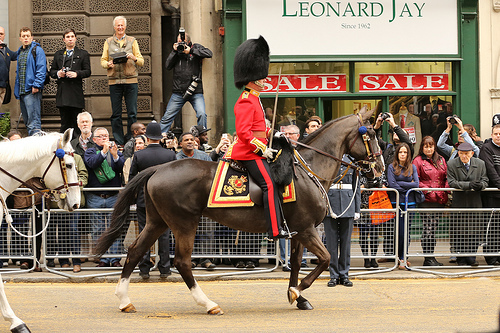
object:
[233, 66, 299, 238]
man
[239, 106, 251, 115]
red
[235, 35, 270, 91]
helmet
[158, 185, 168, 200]
brown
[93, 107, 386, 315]
horse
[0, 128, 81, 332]
horse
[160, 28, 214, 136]
person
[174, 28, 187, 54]
camera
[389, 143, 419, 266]
person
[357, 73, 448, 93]
sign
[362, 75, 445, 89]
sale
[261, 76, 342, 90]
text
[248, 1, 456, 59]
sign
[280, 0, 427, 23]
text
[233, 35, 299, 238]
guard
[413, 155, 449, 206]
coat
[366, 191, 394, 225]
bag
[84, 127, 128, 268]
man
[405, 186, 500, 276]
barrier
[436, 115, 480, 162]
person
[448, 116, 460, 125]
camera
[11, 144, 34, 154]
white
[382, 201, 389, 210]
orange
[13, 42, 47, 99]
jacket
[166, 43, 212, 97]
jacket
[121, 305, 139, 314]
hooves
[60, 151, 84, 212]
face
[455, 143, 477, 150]
hat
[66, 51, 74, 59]
tie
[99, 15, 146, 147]
people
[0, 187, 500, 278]
fence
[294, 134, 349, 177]
reins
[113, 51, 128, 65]
photos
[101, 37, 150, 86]
shirt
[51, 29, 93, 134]
man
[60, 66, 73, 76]
camera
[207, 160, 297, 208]
saddle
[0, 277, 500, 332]
hay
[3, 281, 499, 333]
street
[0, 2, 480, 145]
wall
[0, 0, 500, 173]
city